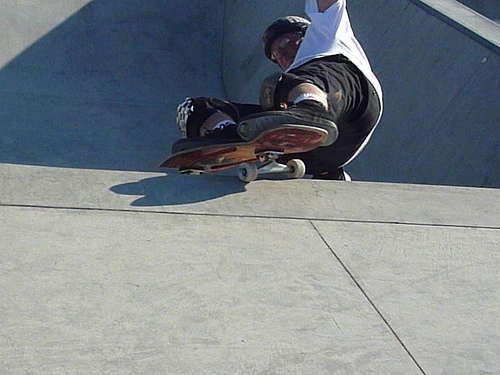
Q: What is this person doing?
A: Skateboarding.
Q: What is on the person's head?
A: Helmet.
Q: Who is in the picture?
A: Skateboarder.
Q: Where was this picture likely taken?
A: Skatepark.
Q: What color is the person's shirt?
A: White.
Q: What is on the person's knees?
A: Knee pads.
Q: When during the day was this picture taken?
A: Daytime.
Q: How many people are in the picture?
A: One.